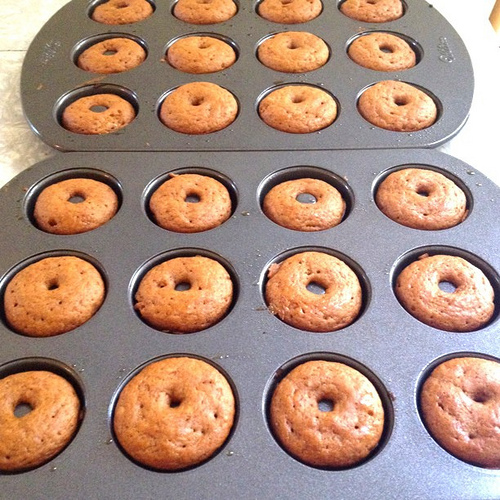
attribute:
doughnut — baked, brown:
[167, 75, 251, 137]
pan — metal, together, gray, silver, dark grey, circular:
[41, 0, 472, 165]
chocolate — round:
[158, 382, 184, 421]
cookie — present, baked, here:
[265, 225, 361, 338]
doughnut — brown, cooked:
[260, 67, 340, 126]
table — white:
[439, 8, 497, 184]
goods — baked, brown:
[96, 17, 489, 467]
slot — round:
[346, 75, 448, 144]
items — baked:
[85, 31, 436, 71]